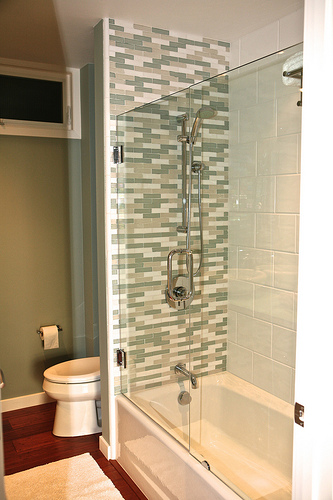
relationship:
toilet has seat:
[42, 356, 102, 440] [43, 357, 102, 385]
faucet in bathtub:
[173, 362, 198, 392] [118, 369, 293, 499]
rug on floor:
[2, 452, 124, 500] [1, 401, 147, 499]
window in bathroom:
[1, 57, 84, 141] [2, 1, 304, 500]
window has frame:
[1, 57, 84, 141] [1, 57, 83, 141]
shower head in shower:
[195, 105, 219, 122] [107, 18, 303, 499]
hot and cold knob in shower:
[173, 286, 195, 302] [107, 18, 303, 499]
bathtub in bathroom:
[118, 369, 293, 499] [2, 1, 304, 500]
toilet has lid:
[42, 356, 102, 440] [43, 357, 102, 385]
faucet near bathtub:
[173, 362, 198, 392] [118, 369, 293, 499]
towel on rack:
[281, 51, 303, 85] [281, 66, 304, 108]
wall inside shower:
[91, 18, 226, 394] [107, 18, 303, 499]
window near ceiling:
[1, 57, 84, 141] [2, 2, 305, 66]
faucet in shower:
[173, 362, 198, 392] [107, 18, 303, 499]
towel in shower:
[281, 51, 303, 85] [107, 18, 303, 499]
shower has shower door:
[107, 18, 303, 499] [116, 42, 303, 499]